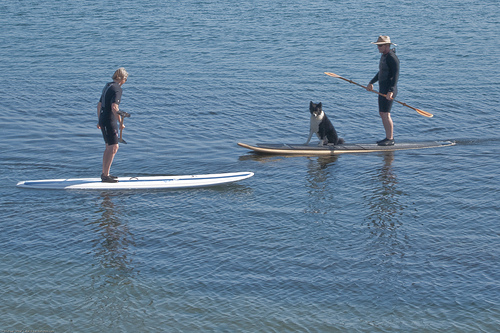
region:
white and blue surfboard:
[11, 167, 260, 193]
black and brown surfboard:
[235, 134, 464, 159]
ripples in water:
[127, 211, 324, 276]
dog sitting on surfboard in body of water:
[234, 91, 464, 159]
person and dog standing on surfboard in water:
[230, 21, 469, 159]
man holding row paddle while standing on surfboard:
[316, 20, 443, 148]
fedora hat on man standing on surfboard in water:
[362, 32, 399, 49]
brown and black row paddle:
[322, 60, 439, 127]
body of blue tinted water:
[1, 0, 488, 329]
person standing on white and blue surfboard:
[87, 61, 142, 184]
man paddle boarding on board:
[66, 60, 204, 198]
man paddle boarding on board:
[229, 26, 448, 159]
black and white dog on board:
[287, 92, 338, 159]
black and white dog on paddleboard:
[287, 86, 342, 161]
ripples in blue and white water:
[209, 234, 251, 279]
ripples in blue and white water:
[296, 235, 346, 280]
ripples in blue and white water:
[43, 267, 96, 313]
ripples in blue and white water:
[163, 42, 216, 92]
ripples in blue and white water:
[429, 11, 483, 59]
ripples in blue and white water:
[16, 43, 49, 87]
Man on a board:
[89, 63, 145, 183]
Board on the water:
[9, 164, 264, 213]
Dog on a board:
[296, 93, 351, 153]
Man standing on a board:
[362, 36, 411, 147]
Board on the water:
[242, 125, 458, 167]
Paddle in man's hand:
[317, 67, 435, 127]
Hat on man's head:
[364, 32, 399, 50]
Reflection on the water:
[364, 154, 409, 262]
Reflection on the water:
[300, 151, 347, 221]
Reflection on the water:
[79, 186, 154, 309]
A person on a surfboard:
[15, 61, 256, 194]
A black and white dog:
[301, 96, 347, 150]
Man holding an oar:
[322, 32, 434, 146]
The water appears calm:
[2, 2, 495, 330]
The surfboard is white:
[11, 167, 258, 197]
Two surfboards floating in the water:
[14, 130, 461, 196]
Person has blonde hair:
[106, 60, 131, 89]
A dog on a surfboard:
[229, 92, 355, 171]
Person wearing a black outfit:
[95, 66, 134, 150]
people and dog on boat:
[14, 15, 461, 210]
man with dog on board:
[238, 15, 465, 152]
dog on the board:
[296, 92, 344, 147]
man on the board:
[326, 28, 443, 141]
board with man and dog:
[244, 136, 466, 168]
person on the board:
[18, 55, 248, 197]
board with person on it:
[16, 166, 266, 196]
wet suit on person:
[95, 86, 127, 144]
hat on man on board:
[371, 33, 397, 50]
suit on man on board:
[369, 53, 398, 109]